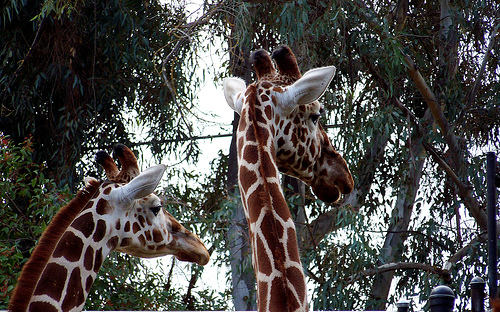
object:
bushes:
[0, 133, 190, 312]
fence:
[79, 107, 500, 312]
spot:
[92, 218, 107, 242]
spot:
[83, 244, 95, 271]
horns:
[94, 142, 140, 183]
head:
[83, 143, 210, 266]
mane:
[246, 84, 292, 312]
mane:
[5, 179, 101, 312]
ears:
[83, 177, 98, 187]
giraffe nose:
[336, 170, 355, 195]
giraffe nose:
[192, 238, 210, 266]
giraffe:
[221, 44, 355, 312]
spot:
[287, 226, 301, 264]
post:
[427, 284, 455, 311]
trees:
[0, 0, 190, 142]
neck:
[235, 126, 307, 312]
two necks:
[338, 15, 420, 76]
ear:
[112, 164, 167, 209]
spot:
[29, 262, 67, 303]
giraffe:
[4, 142, 210, 312]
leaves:
[0, 0, 500, 312]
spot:
[266, 182, 292, 222]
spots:
[25, 301, 59, 312]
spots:
[237, 164, 257, 194]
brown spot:
[239, 164, 259, 195]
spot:
[60, 266, 84, 312]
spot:
[256, 231, 273, 277]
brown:
[248, 193, 262, 208]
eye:
[309, 112, 321, 126]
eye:
[149, 205, 164, 217]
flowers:
[0, 131, 178, 312]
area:
[0, 0, 500, 312]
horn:
[270, 44, 302, 79]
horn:
[249, 49, 276, 82]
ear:
[277, 65, 337, 116]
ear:
[223, 76, 247, 116]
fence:
[394, 275, 486, 311]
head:
[222, 43, 354, 203]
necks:
[5, 204, 112, 312]